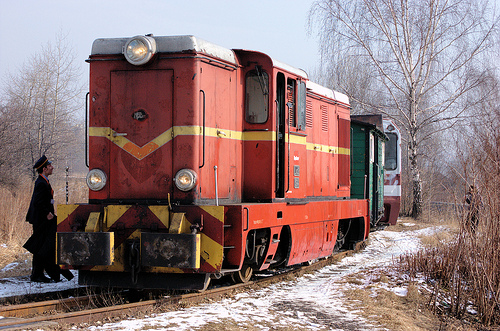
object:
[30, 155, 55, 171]
hat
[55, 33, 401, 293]
train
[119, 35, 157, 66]
light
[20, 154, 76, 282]
conductor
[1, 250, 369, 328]
rail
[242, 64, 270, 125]
window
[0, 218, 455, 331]
snow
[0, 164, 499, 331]
ground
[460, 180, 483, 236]
person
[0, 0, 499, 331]
woods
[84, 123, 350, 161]
line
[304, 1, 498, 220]
tree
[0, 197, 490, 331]
grass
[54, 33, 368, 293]
car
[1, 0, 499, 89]
sky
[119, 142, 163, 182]
heart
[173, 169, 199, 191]
headlights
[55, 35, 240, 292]
front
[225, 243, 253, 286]
wheel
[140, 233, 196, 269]
stoppers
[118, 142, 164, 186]
heart